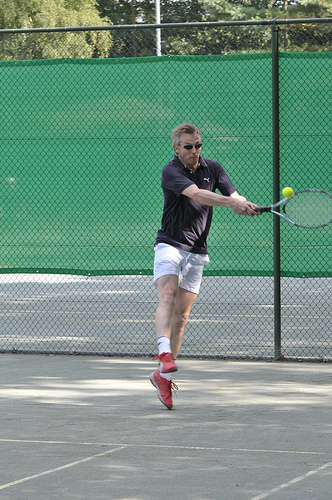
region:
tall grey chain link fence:
[4, 16, 331, 359]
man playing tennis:
[141, 112, 328, 411]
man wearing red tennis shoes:
[129, 112, 330, 415]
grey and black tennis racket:
[249, 173, 331, 240]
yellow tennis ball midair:
[278, 183, 296, 200]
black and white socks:
[151, 333, 178, 372]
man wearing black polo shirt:
[142, 121, 250, 410]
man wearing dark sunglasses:
[137, 117, 256, 410]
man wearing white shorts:
[132, 119, 218, 404]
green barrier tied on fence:
[4, 55, 326, 287]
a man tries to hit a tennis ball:
[128, 107, 330, 404]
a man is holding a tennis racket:
[132, 118, 256, 415]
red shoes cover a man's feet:
[150, 348, 196, 411]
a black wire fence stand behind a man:
[41, 99, 151, 354]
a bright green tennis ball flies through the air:
[264, 181, 303, 212]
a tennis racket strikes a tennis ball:
[244, 182, 330, 235]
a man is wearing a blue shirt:
[136, 114, 251, 397]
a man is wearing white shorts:
[141, 125, 213, 407]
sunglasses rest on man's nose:
[177, 140, 203, 151]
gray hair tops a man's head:
[173, 125, 207, 171]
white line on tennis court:
[85, 447, 131, 463]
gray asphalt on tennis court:
[76, 398, 231, 438]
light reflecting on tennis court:
[44, 367, 220, 396]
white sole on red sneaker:
[145, 373, 165, 403]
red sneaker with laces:
[147, 369, 185, 410]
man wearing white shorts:
[148, 237, 225, 303]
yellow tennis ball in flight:
[276, 184, 297, 209]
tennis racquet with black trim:
[254, 190, 330, 229]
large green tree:
[18, 5, 112, 58]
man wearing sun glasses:
[165, 135, 217, 157]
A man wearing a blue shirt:
[151, 122, 235, 251]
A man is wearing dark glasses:
[180, 140, 200, 147]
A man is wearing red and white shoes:
[146, 335, 176, 406]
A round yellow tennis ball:
[281, 187, 294, 199]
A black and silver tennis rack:
[251, 188, 331, 228]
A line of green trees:
[0, 0, 330, 60]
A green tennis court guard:
[0, 50, 331, 278]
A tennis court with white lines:
[0, 276, 331, 499]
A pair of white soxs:
[157, 335, 172, 383]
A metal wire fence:
[0, 17, 331, 363]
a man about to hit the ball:
[138, 123, 330, 418]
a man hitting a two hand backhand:
[145, 116, 329, 412]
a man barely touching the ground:
[127, 116, 326, 427]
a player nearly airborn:
[138, 122, 330, 431]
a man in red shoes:
[142, 112, 328, 416]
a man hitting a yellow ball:
[129, 86, 320, 443]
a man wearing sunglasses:
[153, 114, 266, 349]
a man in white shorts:
[121, 117, 326, 422]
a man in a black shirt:
[125, 117, 327, 411]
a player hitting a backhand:
[127, 113, 329, 451]